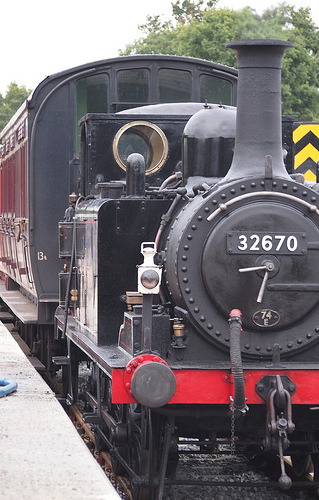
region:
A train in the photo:
[116, 166, 249, 334]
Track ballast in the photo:
[195, 453, 252, 496]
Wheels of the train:
[96, 405, 179, 485]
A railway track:
[185, 444, 249, 496]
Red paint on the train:
[0, 121, 56, 220]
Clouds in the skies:
[51, 6, 116, 50]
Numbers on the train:
[229, 228, 305, 260]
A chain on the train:
[225, 416, 241, 457]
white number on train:
[237, 233, 247, 250]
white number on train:
[249, 233, 259, 250]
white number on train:
[260, 234, 272, 251]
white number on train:
[274, 234, 284, 249]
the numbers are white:
[235, 235, 296, 252]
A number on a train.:
[237, 234, 247, 250]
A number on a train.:
[250, 234, 260, 250]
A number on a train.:
[262, 232, 271, 250]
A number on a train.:
[274, 234, 285, 249]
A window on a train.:
[72, 68, 109, 155]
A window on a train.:
[112, 61, 155, 107]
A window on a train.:
[158, 62, 191, 102]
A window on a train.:
[197, 71, 233, 108]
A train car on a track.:
[8, 51, 259, 372]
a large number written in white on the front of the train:
[233, 233, 298, 254]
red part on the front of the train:
[107, 350, 317, 412]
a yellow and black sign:
[290, 118, 318, 186]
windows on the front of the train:
[71, 58, 238, 153]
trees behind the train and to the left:
[0, 72, 36, 138]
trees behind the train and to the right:
[106, 1, 317, 134]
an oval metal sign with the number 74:
[244, 307, 283, 328]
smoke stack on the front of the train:
[214, 32, 304, 189]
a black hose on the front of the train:
[222, 308, 256, 418]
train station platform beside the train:
[0, 319, 125, 499]